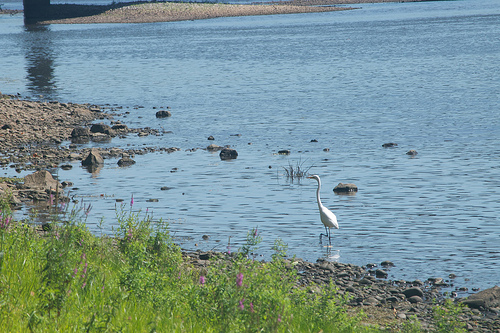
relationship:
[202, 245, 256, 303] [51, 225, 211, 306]
flower in grass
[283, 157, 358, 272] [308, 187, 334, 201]
bird has neck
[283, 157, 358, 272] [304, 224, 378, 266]
bird has leg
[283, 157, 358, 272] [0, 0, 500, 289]
bird in river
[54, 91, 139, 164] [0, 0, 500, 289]
rocks in river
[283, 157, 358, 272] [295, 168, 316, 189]
bird has beak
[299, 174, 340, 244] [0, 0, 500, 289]
bird in river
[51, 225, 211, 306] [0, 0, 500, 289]
grass by river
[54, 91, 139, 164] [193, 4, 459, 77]
rocks in background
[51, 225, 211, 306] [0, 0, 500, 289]
grass near river